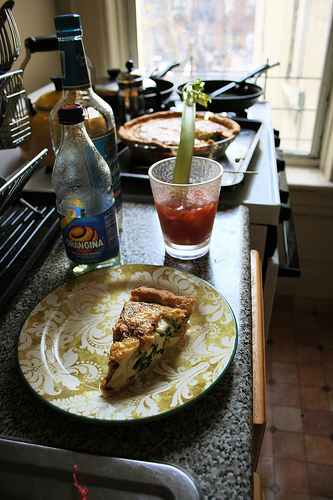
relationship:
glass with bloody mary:
[149, 161, 221, 254] [146, 78, 224, 262]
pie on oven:
[119, 104, 239, 156] [83, 100, 300, 363]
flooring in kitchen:
[259, 293, 331, 498] [6, 3, 329, 497]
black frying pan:
[182, 54, 281, 110] [179, 61, 278, 111]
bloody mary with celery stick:
[146, 78, 224, 262] [169, 83, 210, 185]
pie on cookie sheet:
[119, 104, 239, 156] [105, 118, 262, 190]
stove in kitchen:
[24, 86, 286, 228] [6, 3, 329, 497]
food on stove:
[87, 82, 243, 397] [24, 86, 286, 228]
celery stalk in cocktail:
[172, 79, 210, 184] [143, 77, 221, 259]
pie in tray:
[119, 104, 239, 156] [119, 112, 237, 169]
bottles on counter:
[48, 9, 123, 266] [0, 199, 252, 499]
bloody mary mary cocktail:
[146, 78, 224, 262] [143, 77, 221, 259]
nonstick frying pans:
[119, 55, 278, 104] [128, 60, 287, 114]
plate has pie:
[13, 259, 244, 428] [99, 280, 200, 394]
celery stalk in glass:
[172, 79, 210, 184] [149, 161, 221, 254]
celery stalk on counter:
[172, 79, 210, 184] [0, 199, 252, 499]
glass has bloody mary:
[149, 161, 221, 254] [146, 78, 224, 262]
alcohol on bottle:
[54, 96, 122, 234] [47, 6, 118, 266]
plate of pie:
[13, 259, 244, 428] [96, 289, 190, 392]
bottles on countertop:
[48, 102, 124, 271] [10, 187, 258, 416]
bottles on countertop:
[37, 9, 131, 230] [10, 187, 258, 416]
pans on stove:
[108, 60, 287, 156] [2, 61, 306, 369]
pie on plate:
[102, 285, 197, 392] [13, 259, 244, 428]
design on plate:
[17, 263, 237, 422] [13, 259, 244, 428]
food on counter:
[87, 277, 198, 398] [0, 199, 252, 499]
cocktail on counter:
[143, 77, 221, 259] [0, 199, 252, 499]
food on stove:
[87, 82, 243, 397] [112, 88, 303, 356]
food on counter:
[87, 82, 243, 397] [0, 199, 252, 499]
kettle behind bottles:
[20, 33, 110, 162] [48, 9, 123, 266]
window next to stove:
[135, 0, 331, 154] [20, 80, 297, 349]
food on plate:
[87, 82, 243, 397] [41, 277, 207, 416]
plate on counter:
[13, 259, 244, 428] [0, 199, 252, 499]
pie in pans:
[102, 285, 197, 392] [108, 60, 287, 156]